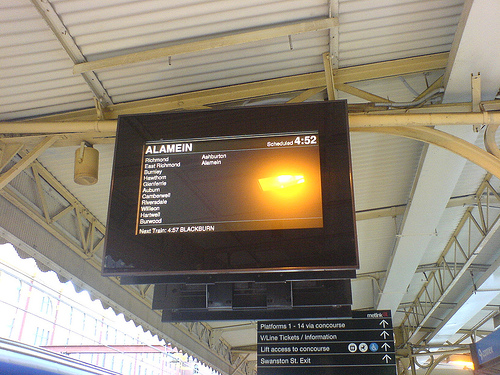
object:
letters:
[261, 323, 265, 331]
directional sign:
[257, 307, 394, 374]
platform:
[0, 243, 500, 374]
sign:
[153, 280, 352, 312]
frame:
[72, 18, 343, 145]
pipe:
[370, 84, 442, 108]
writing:
[140, 156, 173, 166]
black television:
[100, 98, 363, 278]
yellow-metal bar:
[0, 104, 500, 135]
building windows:
[0, 300, 20, 341]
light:
[259, 164, 307, 199]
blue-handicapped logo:
[367, 340, 379, 353]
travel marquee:
[102, 98, 362, 280]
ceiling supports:
[397, 171, 492, 348]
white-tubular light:
[72, 141, 102, 186]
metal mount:
[76, 136, 89, 164]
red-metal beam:
[48, 340, 171, 357]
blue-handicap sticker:
[367, 339, 381, 353]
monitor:
[131, 129, 329, 241]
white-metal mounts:
[319, 48, 346, 101]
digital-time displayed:
[293, 131, 318, 147]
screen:
[127, 124, 327, 241]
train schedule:
[135, 140, 232, 232]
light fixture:
[72, 138, 100, 186]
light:
[443, 352, 476, 369]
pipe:
[349, 109, 499, 128]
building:
[1, 0, 499, 373]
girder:
[41, 338, 168, 358]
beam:
[2, 54, 452, 119]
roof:
[0, 0, 500, 375]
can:
[70, 138, 100, 184]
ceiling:
[2, 0, 497, 374]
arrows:
[379, 315, 394, 332]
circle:
[368, 340, 380, 354]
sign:
[252, 308, 397, 373]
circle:
[358, 339, 371, 354]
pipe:
[0, 118, 118, 138]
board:
[99, 98, 362, 283]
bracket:
[92, 98, 113, 116]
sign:
[464, 326, 498, 373]